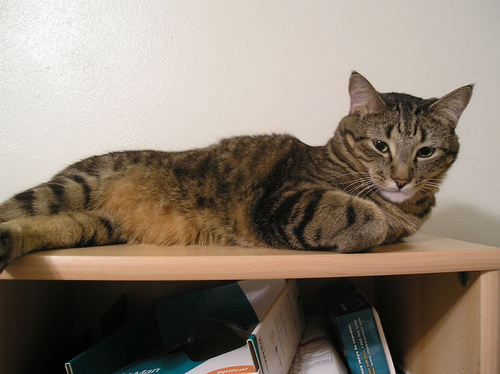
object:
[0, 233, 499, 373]
shelf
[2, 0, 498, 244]
wall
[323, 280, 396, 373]
box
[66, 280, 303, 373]
box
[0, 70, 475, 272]
cat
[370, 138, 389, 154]
eye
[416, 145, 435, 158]
eye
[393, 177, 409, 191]
nose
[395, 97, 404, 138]
stripes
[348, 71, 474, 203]
head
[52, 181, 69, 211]
stripes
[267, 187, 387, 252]
leg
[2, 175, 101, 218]
leg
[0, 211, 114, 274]
leg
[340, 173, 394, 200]
whiskers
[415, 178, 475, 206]
whiskers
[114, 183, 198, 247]
tummy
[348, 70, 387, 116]
ear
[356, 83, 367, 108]
hair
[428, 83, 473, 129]
ear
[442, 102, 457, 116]
hair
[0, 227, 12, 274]
paw